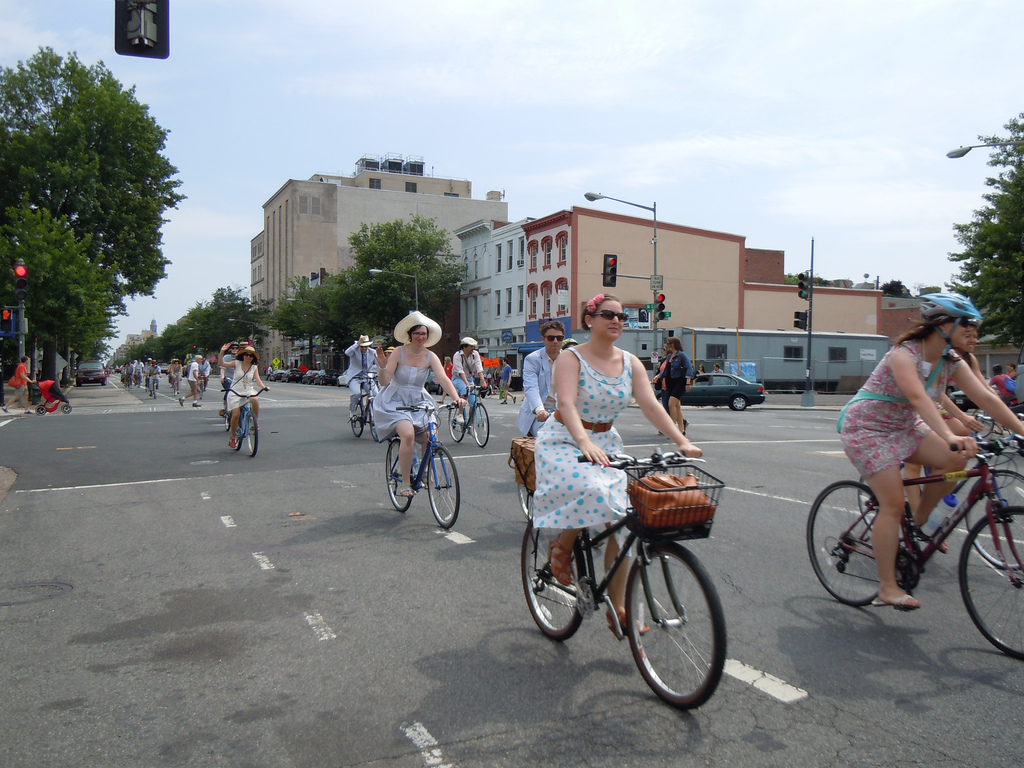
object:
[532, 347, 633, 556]
sundress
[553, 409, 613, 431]
belt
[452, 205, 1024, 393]
building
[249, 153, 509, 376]
building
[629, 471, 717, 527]
purse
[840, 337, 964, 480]
dress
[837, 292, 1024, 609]
woman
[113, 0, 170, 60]
light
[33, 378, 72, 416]
stroller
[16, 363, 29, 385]
shirt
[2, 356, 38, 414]
woman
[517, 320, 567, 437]
man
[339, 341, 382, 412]
suit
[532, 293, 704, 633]
woman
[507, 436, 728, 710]
bike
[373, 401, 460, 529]
riding bike